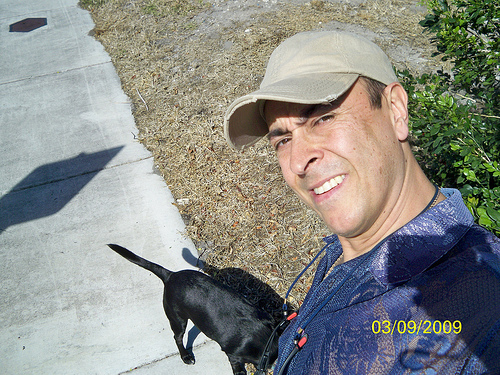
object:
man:
[223, 28, 499, 373]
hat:
[222, 29, 400, 152]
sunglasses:
[250, 309, 310, 374]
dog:
[106, 242, 281, 374]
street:
[0, 6, 233, 374]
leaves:
[436, 42, 485, 120]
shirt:
[273, 188, 500, 374]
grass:
[77, 0, 439, 72]